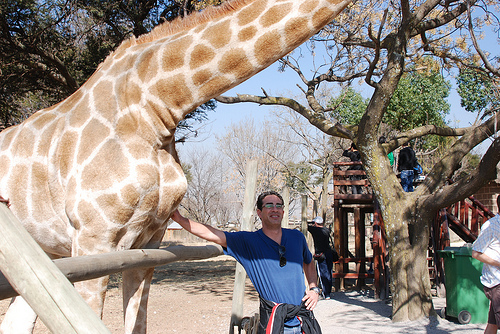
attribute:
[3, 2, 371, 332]
giraffe — tan, standing, brown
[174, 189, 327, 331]
man — smiling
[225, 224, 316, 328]
shirt — blue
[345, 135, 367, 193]
child — playing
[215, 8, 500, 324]
tree — dying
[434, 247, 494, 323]
trash can — green, plastic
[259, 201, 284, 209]
glasses — stylish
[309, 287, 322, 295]
watch — black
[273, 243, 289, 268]
sunglasses — dark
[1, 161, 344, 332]
fence — wooden, large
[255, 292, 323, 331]
jacket — black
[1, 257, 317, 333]
gravel — red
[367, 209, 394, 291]
post — red